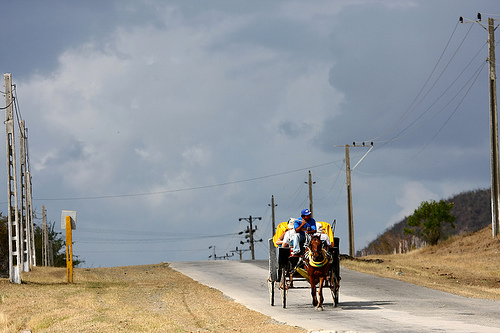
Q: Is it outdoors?
A: Yes, it is outdoors.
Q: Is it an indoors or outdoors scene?
A: It is outdoors.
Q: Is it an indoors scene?
A: No, it is outdoors.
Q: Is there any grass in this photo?
A: Yes, there is grass.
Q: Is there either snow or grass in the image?
A: Yes, there is grass.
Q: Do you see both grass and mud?
A: No, there is grass but no mud.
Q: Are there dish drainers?
A: No, there are no dish drainers.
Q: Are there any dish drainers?
A: No, there are no dish drainers.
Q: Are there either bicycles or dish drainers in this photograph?
A: No, there are no dish drainers or bicycles.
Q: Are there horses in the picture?
A: Yes, there is a horse.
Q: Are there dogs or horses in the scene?
A: Yes, there is a horse.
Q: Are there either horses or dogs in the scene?
A: Yes, there is a horse.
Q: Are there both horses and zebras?
A: No, there is a horse but no zebras.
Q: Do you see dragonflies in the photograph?
A: No, there are no dragonflies.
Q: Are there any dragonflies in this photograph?
A: No, there are no dragonflies.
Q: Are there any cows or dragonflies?
A: No, there are no dragonflies or cows.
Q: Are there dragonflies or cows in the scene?
A: No, there are no dragonflies or cows.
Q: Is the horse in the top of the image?
A: No, the horse is in the bottom of the image.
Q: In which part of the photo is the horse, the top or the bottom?
A: The horse is in the bottom of the image.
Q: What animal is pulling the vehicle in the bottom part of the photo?
A: The horse is pulling the wagon.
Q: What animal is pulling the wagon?
A: The horse is pulling the wagon.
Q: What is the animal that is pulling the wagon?
A: The animal is a horse.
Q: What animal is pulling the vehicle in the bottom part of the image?
A: The animal is a horse.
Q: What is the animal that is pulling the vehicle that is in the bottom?
A: The animal is a horse.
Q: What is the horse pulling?
A: The horse is pulling the wagon.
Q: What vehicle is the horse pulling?
A: The horse is pulling the wagon.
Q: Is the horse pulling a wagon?
A: Yes, the horse is pulling a wagon.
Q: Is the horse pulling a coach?
A: No, the horse is pulling a wagon.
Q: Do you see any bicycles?
A: No, there are no bicycles.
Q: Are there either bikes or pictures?
A: No, there are no bikes or pictures.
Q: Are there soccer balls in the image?
A: No, there are no soccer balls.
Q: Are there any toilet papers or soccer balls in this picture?
A: No, there are no soccer balls or toilet papers.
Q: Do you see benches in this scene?
A: No, there are no benches.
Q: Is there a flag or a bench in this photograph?
A: No, there are no benches or flags.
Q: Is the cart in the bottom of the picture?
A: Yes, the cart is in the bottom of the image.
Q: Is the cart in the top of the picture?
A: No, the cart is in the bottom of the image.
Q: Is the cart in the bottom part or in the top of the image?
A: The cart is in the bottom of the image.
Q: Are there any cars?
A: No, there are no cars.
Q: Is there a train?
A: No, there are no trains.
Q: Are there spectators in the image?
A: No, there are no spectators.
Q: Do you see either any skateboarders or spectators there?
A: No, there are no spectators or skateboarders.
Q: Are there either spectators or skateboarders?
A: No, there are no spectators or skateboarders.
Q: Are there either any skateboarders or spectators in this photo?
A: No, there are no spectators or skateboarders.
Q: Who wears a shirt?
A: The man wears a shirt.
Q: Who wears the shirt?
A: The man wears a shirt.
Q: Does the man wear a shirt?
A: Yes, the man wears a shirt.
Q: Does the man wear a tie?
A: No, the man wears a shirt.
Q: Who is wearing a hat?
A: The man is wearing a hat.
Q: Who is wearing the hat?
A: The man is wearing a hat.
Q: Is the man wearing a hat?
A: Yes, the man is wearing a hat.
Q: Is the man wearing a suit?
A: No, the man is wearing a hat.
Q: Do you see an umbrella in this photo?
A: No, there are no umbrellas.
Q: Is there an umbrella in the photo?
A: No, there are no umbrellas.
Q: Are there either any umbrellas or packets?
A: No, there are no umbrellas or packets.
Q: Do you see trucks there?
A: No, there are no trucks.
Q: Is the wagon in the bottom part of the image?
A: Yes, the wagon is in the bottom of the image.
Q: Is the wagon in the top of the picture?
A: No, the wagon is in the bottom of the image.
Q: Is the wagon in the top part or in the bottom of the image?
A: The wagon is in the bottom of the image.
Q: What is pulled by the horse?
A: The wagon is pulled by the horse.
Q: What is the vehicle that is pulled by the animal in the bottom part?
A: The vehicle is a wagon.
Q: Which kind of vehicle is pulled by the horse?
A: The vehicle is a wagon.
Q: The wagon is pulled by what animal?
A: The wagon is pulled by the horse.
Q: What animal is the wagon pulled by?
A: The wagon is pulled by the horse.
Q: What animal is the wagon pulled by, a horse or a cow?
A: The wagon is pulled by a horse.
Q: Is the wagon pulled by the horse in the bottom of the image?
A: Yes, the wagon is pulled by the horse.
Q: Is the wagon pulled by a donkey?
A: No, the wagon is pulled by the horse.